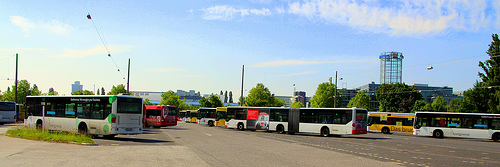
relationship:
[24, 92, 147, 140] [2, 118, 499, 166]
bus in lot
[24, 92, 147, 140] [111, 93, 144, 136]
bus has back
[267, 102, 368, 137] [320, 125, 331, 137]
bus has wheel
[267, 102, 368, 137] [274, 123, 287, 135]
bus has wheel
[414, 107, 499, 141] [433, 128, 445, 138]
bus has wheel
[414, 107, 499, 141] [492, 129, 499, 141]
bus has wheel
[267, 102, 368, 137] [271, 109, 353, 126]
bus has windows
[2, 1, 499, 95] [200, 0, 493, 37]
sky has cloud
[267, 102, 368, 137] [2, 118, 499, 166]
bus in lot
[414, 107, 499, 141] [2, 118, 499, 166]
bus in lot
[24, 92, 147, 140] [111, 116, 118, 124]
bus has tail light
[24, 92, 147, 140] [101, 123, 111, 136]
bus has marking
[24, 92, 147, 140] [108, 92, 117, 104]
bus has marking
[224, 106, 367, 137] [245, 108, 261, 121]
bus has panel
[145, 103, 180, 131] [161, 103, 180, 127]
bus has back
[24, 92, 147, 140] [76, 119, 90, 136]
bus has wheel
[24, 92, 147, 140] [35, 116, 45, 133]
bus has wheel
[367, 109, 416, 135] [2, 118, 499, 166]
bus in lot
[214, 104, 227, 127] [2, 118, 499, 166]
bus in lot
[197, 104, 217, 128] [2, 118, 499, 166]
bus in lot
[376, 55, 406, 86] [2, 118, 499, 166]
tower above lot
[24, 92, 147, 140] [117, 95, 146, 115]
bus has window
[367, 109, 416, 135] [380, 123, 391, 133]
bus has wheel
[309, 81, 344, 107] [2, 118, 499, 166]
tree above lot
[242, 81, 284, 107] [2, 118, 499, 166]
tree above lot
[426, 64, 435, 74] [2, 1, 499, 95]
balloon in sky